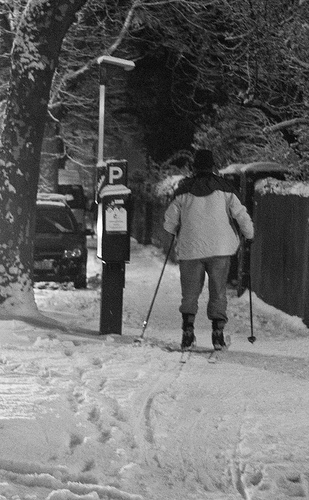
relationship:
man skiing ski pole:
[161, 149, 255, 353] [246, 235, 256, 345]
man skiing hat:
[161, 149, 255, 353] [193, 151, 211, 166]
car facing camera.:
[30, 191, 87, 290] [0, 149, 299, 466]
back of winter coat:
[173, 191, 239, 255] [164, 188, 251, 258]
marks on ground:
[53, 354, 176, 462] [14, 320, 132, 444]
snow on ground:
[0, 0, 309, 499] [133, 354, 239, 468]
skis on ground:
[178, 332, 197, 365] [1, 234, 307, 497]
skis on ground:
[208, 333, 233, 363] [1, 234, 307, 497]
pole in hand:
[249, 238, 253, 340] [167, 229, 178, 236]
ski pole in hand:
[133, 234, 171, 341] [244, 237, 254, 244]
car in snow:
[8, 184, 102, 289] [28, 189, 108, 353]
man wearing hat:
[161, 149, 255, 353] [190, 149, 215, 170]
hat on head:
[190, 149, 215, 170] [194, 149, 215, 174]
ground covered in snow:
[1, 234, 307, 497] [3, 205, 307, 487]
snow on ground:
[0, 0, 309, 499] [1, 234, 307, 497]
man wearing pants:
[161, 149, 255, 353] [176, 253, 232, 323]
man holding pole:
[161, 149, 255, 353] [249, 238, 253, 340]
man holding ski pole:
[161, 149, 255, 353] [133, 234, 171, 341]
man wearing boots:
[161, 149, 255, 353] [171, 304, 232, 351]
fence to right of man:
[129, 182, 308, 332] [161, 149, 255, 353]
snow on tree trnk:
[65, 369, 195, 418] [0, 0, 86, 324]